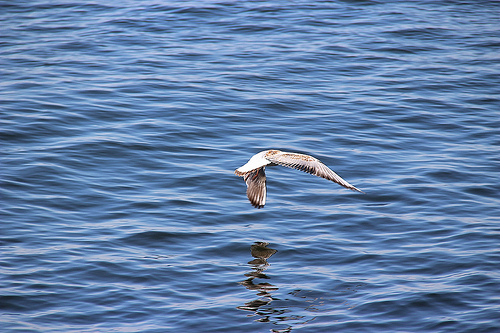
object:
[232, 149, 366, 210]
bird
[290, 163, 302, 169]
wing tips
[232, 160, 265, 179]
tail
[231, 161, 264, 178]
feathers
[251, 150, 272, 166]
back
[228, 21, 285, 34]
waves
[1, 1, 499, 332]
water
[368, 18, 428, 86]
ripples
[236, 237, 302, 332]
reflection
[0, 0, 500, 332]
image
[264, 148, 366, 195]
wing